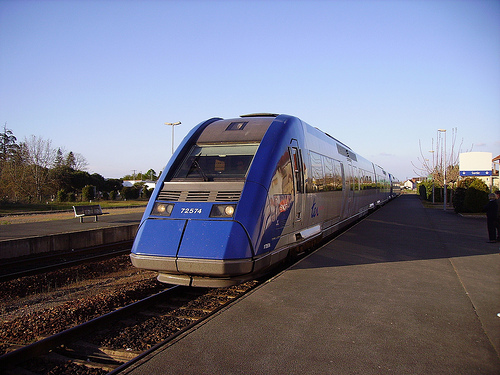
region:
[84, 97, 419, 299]
blue and grey train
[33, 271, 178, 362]
gravel around the tracks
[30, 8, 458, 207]
blue and white gradient sky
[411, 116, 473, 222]
small tree with no leaves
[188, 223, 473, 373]
dark grey pavement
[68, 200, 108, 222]
small bench beside the train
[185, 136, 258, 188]
small rectangular windshield of a train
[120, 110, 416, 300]
the train is very long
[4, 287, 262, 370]
train tracks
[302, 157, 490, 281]
shadow cast by the train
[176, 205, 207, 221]
The white numbers on the front of the train.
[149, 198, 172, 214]
The left headlight area of the train.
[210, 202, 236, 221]
The right headlight area of the train.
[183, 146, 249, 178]
The front window of the train.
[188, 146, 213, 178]
The windshield wiper on the front window.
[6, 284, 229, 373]
The tracks in front of the train.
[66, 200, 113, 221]
The bench on the platform.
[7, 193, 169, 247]
The platform area the bench is located on.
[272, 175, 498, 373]
The cement area to the right of the train.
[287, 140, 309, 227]
The door on the side of the train.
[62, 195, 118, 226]
empty bench at train station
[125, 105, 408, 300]
blue and silver train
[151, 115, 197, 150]
light post at train stop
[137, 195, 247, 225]
two head lights on train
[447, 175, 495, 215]
hedge at train stop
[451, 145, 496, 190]
sign post at train station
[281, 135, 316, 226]
train door on blue and silver train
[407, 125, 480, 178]
tree without leaves at train station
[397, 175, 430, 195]
building located behind train station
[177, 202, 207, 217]
72574 on the front of the train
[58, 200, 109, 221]
Empty bench on the platform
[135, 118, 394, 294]
Blue and gray train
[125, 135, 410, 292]
This is a passenger train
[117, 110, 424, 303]
The train is on the tracks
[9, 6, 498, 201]
The sky is clear and blue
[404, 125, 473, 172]
No leaves on the trees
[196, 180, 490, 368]
Train platform made of concrete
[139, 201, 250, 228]
Two headlights on front of the train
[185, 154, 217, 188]
Windshield wiper on the train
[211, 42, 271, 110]
part of the sky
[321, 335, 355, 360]
part of a floor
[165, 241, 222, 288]
edge of a train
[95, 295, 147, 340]
edge of a train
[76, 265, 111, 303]
part of a ground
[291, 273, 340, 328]
part of a floor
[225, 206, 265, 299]
edge of a train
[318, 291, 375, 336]
part of a floor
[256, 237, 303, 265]
edge of a train